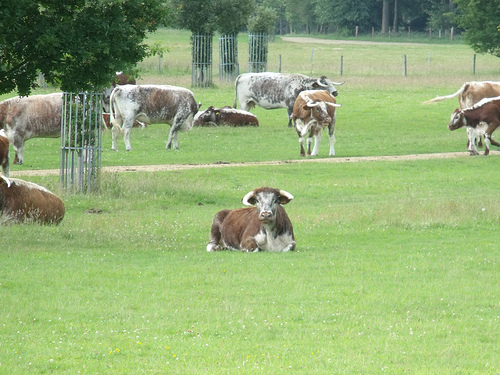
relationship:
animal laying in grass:
[190, 104, 274, 136] [10, 84, 498, 374]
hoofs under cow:
[250, 247, 289, 253] [204, 184, 300, 259]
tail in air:
[421, 81, 469, 103] [332, 9, 431, 111]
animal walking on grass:
[204, 184, 312, 259] [9, 44, 499, 364]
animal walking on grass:
[446, 90, 499, 161] [9, 44, 499, 364]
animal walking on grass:
[283, 80, 363, 156] [9, 44, 499, 364]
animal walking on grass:
[2, 161, 69, 235] [9, 44, 499, 364]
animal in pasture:
[204, 184, 312, 259] [2, 260, 494, 352]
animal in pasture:
[283, 80, 363, 156] [2, 260, 494, 352]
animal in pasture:
[190, 104, 274, 136] [2, 260, 494, 352]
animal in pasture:
[446, 90, 499, 161] [2, 260, 494, 352]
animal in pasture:
[2, 161, 69, 235] [2, 260, 494, 352]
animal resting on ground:
[204, 184, 312, 259] [0, 155, 500, 373]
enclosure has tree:
[45, 83, 110, 189] [3, 4, 138, 196]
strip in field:
[85, 148, 460, 180] [88, 132, 478, 371]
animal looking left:
[283, 80, 363, 156] [1, 2, 215, 372]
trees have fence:
[244, 5, 276, 75] [245, 29, 270, 74]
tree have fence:
[214, 0, 256, 81] [218, 30, 240, 81]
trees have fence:
[160, 0, 222, 88] [191, 31, 215, 88]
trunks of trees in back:
[52, 103, 129, 303] [81, 82, 467, 242]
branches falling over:
[36, 2, 143, 151] [175, 80, 400, 174]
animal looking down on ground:
[106, 71, 207, 156] [193, 197, 361, 374]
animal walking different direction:
[446, 90, 499, 161] [12, 246, 448, 372]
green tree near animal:
[2, 0, 172, 195] [204, 184, 312, 259]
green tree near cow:
[2, 0, 172, 195] [288, 89, 343, 158]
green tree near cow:
[2, 0, 172, 195] [109, 83, 210, 150]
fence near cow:
[312, 50, 472, 128] [135, 168, 364, 321]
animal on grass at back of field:
[231, 60, 344, 115] [8, 71, 499, 371]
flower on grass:
[70, 344, 136, 366] [255, 197, 464, 310]